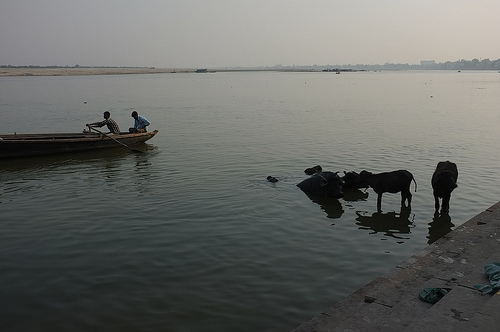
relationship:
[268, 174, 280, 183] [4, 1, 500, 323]
stone in water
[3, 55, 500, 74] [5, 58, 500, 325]
line in waters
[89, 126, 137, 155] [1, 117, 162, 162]
oar on boat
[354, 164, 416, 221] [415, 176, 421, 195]
cow has tail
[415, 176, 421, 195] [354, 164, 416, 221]
tail on cow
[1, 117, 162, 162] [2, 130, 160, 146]
boat has edge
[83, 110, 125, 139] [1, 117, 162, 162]
man in boat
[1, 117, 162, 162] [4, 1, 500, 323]
boat in water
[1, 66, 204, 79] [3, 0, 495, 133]
land in distance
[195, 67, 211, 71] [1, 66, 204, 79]
house on land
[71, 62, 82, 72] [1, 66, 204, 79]
house on land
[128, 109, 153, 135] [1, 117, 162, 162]
man in boat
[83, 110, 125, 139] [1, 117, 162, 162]
man rowing boat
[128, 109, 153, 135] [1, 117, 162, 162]
man back of boat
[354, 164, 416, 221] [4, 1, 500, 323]
cow in water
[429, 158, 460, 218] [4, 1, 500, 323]
cow in water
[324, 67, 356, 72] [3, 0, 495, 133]
building in distance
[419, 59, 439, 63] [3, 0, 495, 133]
building in distance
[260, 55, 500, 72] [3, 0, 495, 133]
trees in distance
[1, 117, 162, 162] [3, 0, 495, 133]
boat on horizon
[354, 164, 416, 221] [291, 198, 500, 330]
cow next to wall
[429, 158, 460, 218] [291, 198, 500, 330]
cow next to wall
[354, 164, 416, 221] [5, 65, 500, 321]
cow in lake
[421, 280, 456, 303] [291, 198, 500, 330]
sandals on wall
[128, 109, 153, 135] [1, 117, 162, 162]
man rowing boat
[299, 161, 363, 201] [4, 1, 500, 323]
trash in water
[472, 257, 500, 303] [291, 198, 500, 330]
clothes on wall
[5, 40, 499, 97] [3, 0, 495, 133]
view in distance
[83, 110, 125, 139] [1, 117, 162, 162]
man on boat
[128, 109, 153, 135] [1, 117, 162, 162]
man on boat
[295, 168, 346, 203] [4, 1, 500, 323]
cow in water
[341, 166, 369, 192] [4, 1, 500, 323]
cow in water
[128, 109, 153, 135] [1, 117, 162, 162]
person on boat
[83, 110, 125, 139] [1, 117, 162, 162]
person on boat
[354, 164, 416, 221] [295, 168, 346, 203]
cow looking at cow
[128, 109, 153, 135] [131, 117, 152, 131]
man wearing shirt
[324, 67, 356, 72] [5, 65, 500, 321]
building by lake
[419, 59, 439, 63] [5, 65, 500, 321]
building by lake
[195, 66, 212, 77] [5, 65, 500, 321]
building by lake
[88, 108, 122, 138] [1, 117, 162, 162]
person on boat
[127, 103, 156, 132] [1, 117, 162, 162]
person on boat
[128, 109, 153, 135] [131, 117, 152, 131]
man in shirt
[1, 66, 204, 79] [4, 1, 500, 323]
land next to water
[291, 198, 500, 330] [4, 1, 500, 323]
wall by water